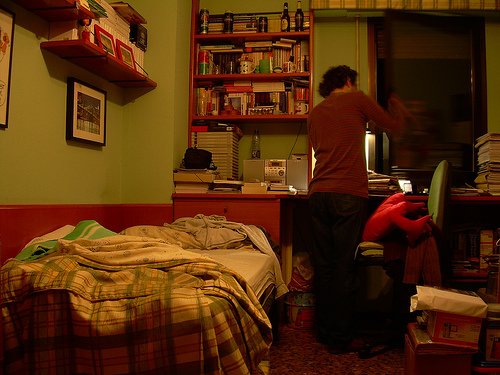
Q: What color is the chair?
A: Green.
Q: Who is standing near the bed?
A: A woman.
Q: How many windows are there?
A: One.